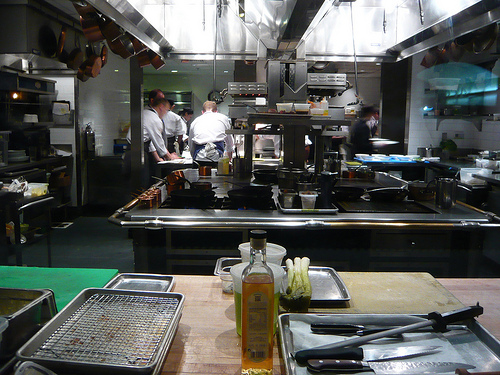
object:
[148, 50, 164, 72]
pot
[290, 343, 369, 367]
handle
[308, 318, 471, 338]
knife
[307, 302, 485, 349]
thermometer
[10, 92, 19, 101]
light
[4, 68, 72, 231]
stove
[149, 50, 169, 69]
hanging pot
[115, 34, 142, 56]
pot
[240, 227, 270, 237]
black cap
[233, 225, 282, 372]
oil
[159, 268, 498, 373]
wooden surface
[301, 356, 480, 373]
knife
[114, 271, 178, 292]
metal tray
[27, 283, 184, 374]
metal tray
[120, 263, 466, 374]
table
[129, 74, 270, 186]
person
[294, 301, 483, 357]
knife sharpener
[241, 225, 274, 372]
bottle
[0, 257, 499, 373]
counter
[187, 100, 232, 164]
person/white shirt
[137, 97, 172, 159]
person/white shirt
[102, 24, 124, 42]
pot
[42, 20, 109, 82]
pot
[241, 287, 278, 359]
label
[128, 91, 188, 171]
man